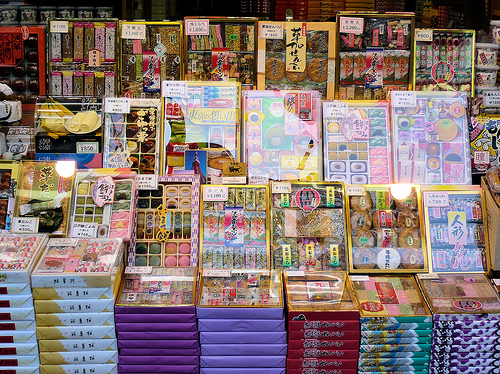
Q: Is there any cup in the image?
A: No, there are no cups.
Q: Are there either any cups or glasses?
A: No, there are no cups or glasses.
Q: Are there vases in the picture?
A: No, there are no vases.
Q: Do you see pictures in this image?
A: No, there are no pictures.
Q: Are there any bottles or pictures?
A: No, there are no pictures or bottles.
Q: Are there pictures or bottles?
A: No, there are no pictures or bottles.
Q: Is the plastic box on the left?
A: Yes, the box is on the left of the image.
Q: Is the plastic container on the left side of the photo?
A: Yes, the box is on the left of the image.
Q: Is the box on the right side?
A: No, the box is on the left of the image.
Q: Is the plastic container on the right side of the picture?
A: No, the box is on the left of the image.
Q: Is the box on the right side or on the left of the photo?
A: The box is on the left of the image.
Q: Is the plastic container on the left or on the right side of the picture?
A: The box is on the left of the image.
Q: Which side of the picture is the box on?
A: The box is on the left of the image.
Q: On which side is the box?
A: The box is on the left of the image.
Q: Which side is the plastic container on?
A: The box is on the left of the image.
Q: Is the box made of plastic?
A: Yes, the box is made of plastic.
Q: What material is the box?
A: The box is made of plastic.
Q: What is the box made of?
A: The box is made of plastic.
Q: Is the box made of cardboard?
A: No, the box is made of plastic.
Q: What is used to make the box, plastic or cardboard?
A: The box is made of plastic.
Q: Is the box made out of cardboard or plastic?
A: The box is made of plastic.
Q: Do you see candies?
A: Yes, there are candies.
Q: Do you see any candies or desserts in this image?
A: Yes, there are candies.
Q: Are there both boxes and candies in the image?
A: Yes, there are both candies and a box.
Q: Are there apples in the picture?
A: No, there are no apples.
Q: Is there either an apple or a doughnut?
A: No, there are no apples or donuts.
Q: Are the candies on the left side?
A: Yes, the candies are on the left of the image.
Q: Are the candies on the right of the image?
A: No, the candies are on the left of the image.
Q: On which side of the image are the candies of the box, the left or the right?
A: The candies are on the left of the image.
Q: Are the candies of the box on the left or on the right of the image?
A: The candies are on the left of the image.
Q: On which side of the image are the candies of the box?
A: The candies are on the left of the image.